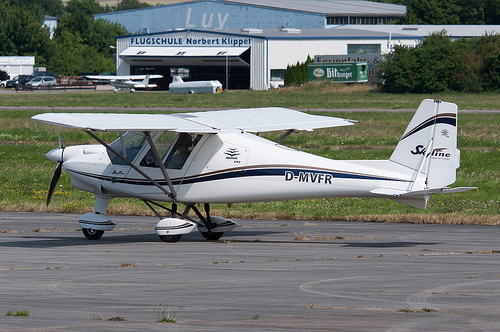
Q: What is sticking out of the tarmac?
A: Grass.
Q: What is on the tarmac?
A: Airplane.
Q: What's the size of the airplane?
A: Small.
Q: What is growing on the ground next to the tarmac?
A: Grass.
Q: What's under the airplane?
A: Wheels.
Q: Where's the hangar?
A: Behind airplane.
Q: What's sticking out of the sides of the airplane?
A: Wings.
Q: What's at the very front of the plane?
A: Propeller.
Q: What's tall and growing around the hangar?
A: Trees.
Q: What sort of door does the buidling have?
A: A garage door.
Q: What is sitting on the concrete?
A: A plane.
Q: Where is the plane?
A: On a runway.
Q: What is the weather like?
A: Sunny.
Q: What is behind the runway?
A: Grass.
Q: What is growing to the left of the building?
A: Trees.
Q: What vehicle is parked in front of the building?
A: A van.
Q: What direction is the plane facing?
A: Sideways.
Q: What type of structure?
A: Building.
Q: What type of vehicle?
A: Plane.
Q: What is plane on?
A: Runway.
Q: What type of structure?
A: Building.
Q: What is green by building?
A: Bushes.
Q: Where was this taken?
A: Air field.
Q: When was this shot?
A: Daytime.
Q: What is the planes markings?
A: D-mvfr.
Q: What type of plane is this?
A: Propeller.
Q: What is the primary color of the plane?
A: White.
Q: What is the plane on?
A: Runway.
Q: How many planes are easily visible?
A: 1.